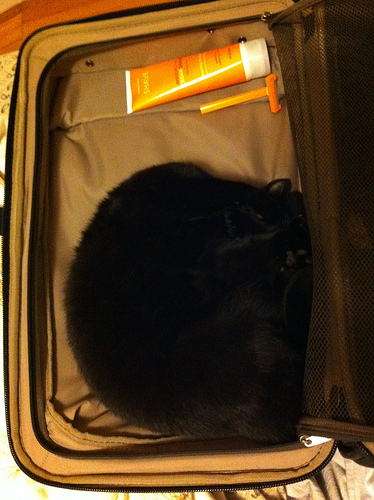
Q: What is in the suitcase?
A: A lotion.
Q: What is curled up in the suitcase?
A: Black cat.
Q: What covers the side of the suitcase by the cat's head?
A: Black mesh.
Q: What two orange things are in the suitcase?
A: Razor and tube.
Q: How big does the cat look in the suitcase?
A: Big.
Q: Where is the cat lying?
A: Inside the suitcase.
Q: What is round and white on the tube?
A: Cap.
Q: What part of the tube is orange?
A: Body.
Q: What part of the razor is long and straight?
A: Handle.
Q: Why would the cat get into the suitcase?
A: It is open.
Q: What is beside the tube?
A: A razor blade.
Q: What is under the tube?
A: A suitcase.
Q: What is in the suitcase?
A: A cat.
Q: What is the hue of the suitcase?
A: Golden brown.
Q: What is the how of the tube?
A: Yellow and white.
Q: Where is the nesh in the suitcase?
A: On the top.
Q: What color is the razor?
A: Yellow.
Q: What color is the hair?
A: Black.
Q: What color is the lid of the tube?
A: White.